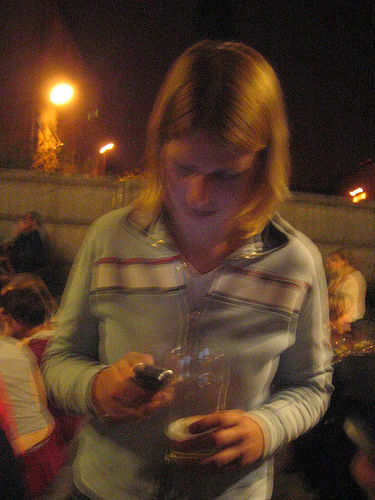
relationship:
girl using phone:
[40, 40, 335, 499] [134, 359, 173, 394]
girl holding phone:
[45, 40, 338, 499] [134, 359, 173, 394]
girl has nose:
[40, 40, 335, 499] [184, 175, 216, 206]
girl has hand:
[40, 40, 335, 499] [88, 352, 173, 424]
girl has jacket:
[40, 40, 335, 499] [43, 205, 334, 499]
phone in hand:
[134, 359, 173, 394] [88, 352, 173, 424]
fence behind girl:
[1, 166, 374, 290] [45, 40, 338, 499]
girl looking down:
[45, 40, 338, 499] [10, 405, 245, 499]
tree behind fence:
[23, 111, 66, 171] [1, 166, 374, 290]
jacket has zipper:
[43, 205, 334, 499] [180, 303, 205, 352]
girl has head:
[40, 40, 335, 499] [137, 38, 288, 242]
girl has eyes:
[40, 40, 335, 499] [172, 158, 252, 183]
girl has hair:
[40, 40, 335, 499] [139, 36, 294, 241]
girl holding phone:
[40, 40, 335, 499] [134, 359, 173, 394]